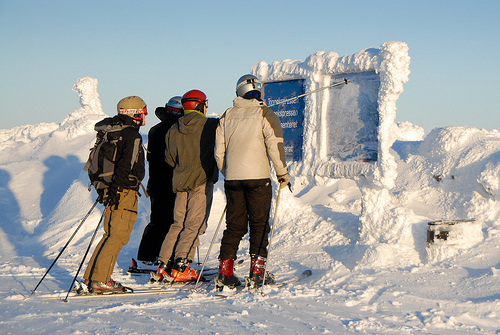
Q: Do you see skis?
A: Yes, there are skis.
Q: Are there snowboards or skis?
A: Yes, there are skis.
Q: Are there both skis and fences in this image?
A: No, there are skis but no fences.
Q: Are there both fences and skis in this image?
A: No, there are skis but no fences.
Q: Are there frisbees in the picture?
A: No, there are no frisbees.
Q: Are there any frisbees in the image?
A: No, there are no frisbees.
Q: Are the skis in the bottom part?
A: Yes, the skis are in the bottom of the image.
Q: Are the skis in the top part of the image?
A: No, the skis are in the bottom of the image.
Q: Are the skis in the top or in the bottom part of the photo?
A: The skis are in the bottom of the image.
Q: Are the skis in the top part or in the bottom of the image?
A: The skis are in the bottom of the image.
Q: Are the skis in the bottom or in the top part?
A: The skis are in the bottom of the image.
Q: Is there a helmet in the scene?
A: Yes, there is a helmet.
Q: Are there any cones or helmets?
A: Yes, there is a helmet.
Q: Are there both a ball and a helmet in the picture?
A: No, there is a helmet but no balls.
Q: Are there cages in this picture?
A: No, there are no cages.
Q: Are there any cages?
A: No, there are no cages.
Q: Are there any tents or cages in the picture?
A: No, there are no cages or tents.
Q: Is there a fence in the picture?
A: No, there are no fences.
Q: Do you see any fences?
A: No, there are no fences.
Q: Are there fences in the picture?
A: No, there are no fences.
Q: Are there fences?
A: No, there are no fences.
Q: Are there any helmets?
A: Yes, there is a helmet.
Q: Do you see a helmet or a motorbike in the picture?
A: Yes, there is a helmet.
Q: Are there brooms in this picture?
A: No, there are no brooms.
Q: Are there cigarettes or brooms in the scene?
A: No, there are no brooms or cigarettes.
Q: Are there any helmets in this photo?
A: Yes, there is a helmet.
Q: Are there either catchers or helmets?
A: Yes, there is a helmet.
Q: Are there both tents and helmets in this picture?
A: No, there is a helmet but no tents.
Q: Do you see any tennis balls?
A: No, there are no tennis balls.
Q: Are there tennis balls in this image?
A: No, there are no tennis balls.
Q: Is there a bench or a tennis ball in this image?
A: No, there are no tennis balls or benches.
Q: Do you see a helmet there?
A: Yes, there is a helmet.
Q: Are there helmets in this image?
A: Yes, there is a helmet.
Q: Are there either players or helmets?
A: Yes, there is a helmet.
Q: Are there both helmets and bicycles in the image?
A: No, there is a helmet but no bikes.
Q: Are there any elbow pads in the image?
A: No, there are no elbow pads.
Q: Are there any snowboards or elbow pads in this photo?
A: No, there are no elbow pads or snowboards.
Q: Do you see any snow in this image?
A: Yes, there is snow.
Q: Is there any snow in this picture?
A: Yes, there is snow.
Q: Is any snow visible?
A: Yes, there is snow.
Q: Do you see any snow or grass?
A: Yes, there is snow.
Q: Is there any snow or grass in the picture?
A: Yes, there is snow.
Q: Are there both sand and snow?
A: No, there is snow but no sand.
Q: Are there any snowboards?
A: No, there are no snowboards.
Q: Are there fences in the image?
A: No, there are no fences.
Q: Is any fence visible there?
A: No, there are no fences.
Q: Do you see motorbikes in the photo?
A: No, there are no motorbikes.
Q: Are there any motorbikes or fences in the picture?
A: No, there are no motorbikes or fences.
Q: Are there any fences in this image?
A: No, there are no fences.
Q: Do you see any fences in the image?
A: No, there are no fences.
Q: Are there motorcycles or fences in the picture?
A: No, there are no fences or motorcycles.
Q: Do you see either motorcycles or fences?
A: No, there are no fences or motorcycles.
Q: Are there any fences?
A: No, there are no fences.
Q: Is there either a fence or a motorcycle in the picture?
A: No, there are no fences or motorcycles.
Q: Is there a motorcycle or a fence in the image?
A: No, there are no fences or motorcycles.